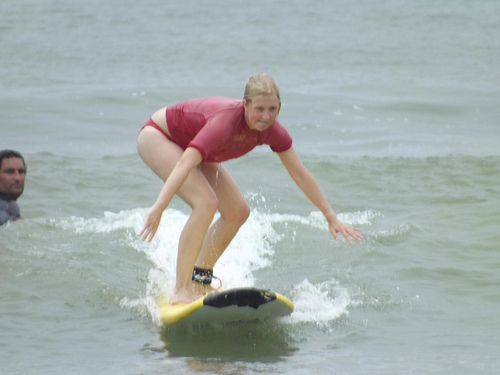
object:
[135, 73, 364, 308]
girl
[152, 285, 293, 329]
surfboard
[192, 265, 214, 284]
ankle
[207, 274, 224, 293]
rope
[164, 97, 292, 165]
shirt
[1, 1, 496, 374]
ocean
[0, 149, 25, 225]
man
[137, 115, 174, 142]
bathing suit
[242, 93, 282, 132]
face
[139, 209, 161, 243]
hand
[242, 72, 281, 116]
hair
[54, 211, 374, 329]
wave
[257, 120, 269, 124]
lip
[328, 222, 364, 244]
hand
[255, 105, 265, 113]
eye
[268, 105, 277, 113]
eye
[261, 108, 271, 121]
nose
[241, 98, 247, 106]
right ear